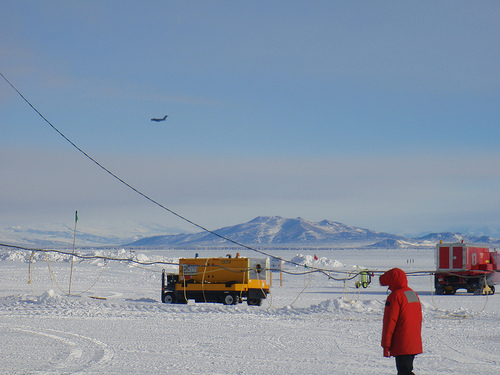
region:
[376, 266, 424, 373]
The man is wearing a red coat.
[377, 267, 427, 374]
The man is wearing black pants.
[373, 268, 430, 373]
The man is standing in the snow.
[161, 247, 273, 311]
The yellow truck is on the snow.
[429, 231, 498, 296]
The red truck is on the snow.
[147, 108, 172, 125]
The airplane is in the sky.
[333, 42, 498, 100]
The sky is clear.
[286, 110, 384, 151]
The sky is blue.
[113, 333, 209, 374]
The snow is white.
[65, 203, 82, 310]
The pole in the background is tall.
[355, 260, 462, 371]
a red winter jacket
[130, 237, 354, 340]
a yellow truck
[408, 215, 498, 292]
a red and gray vehicle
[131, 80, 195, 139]
a plane in the sky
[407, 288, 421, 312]
gray patch on red jacket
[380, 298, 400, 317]
black patch on red jacket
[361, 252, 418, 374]
red jacket and black pants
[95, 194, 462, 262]
a mountain in the background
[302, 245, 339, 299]
a red flag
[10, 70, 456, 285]
a long black cord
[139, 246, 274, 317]
yellow truck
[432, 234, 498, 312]
red truck in snow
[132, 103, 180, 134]
plane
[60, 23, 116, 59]
white clouds in blue sky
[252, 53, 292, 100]
white clouds in blue sky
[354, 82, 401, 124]
white clouds in blue sky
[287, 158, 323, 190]
white clouds in blue sky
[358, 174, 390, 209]
white clouds in blue sky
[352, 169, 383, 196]
white clouds in blue sky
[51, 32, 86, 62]
white clouds in blue sky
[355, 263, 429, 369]
person with red jacket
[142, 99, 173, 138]
airplane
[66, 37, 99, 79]
white clouds in blue sky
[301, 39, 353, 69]
white clouds in blue sky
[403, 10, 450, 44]
white clouds in blue sky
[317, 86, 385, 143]
white clouds in blue sky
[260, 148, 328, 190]
white clouds in blue sky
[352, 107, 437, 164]
white clouds in blue sky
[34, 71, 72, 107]
white clouds in blue sky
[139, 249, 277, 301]
yellow truck in snow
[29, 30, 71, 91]
white clouds in blue sky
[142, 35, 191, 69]
white clouds in blue sky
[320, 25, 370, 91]
white clouds in blue sky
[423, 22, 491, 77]
white clouds in blue sky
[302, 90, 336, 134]
white clouds in blue sky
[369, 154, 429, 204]
white clouds in blue sky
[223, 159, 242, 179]
white clouds in blue sky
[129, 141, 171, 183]
white clouds in blue sky